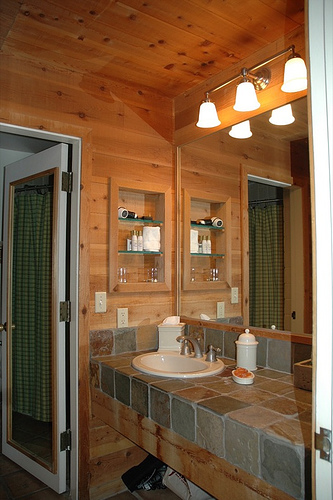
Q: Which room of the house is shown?
A: It is a bathroom.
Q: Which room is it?
A: It is a bathroom.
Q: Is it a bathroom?
A: Yes, it is a bathroom.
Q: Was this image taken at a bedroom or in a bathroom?
A: It was taken at a bathroom.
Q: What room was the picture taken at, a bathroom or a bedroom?
A: It was taken at a bathroom.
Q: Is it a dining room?
A: No, it is a bathroom.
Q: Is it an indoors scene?
A: Yes, it is indoors.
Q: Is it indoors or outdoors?
A: It is indoors.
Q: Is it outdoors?
A: No, it is indoors.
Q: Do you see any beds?
A: No, there are no beds.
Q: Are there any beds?
A: No, there are no beds.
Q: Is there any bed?
A: No, there are no beds.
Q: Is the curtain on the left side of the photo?
A: Yes, the curtain is on the left of the image.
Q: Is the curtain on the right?
A: No, the curtain is on the left of the image.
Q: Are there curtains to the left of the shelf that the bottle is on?
A: Yes, there is a curtain to the left of the shelf.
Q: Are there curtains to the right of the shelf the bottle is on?
A: No, the curtain is to the left of the shelf.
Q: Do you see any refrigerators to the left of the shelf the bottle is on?
A: No, there is a curtain to the left of the shelf.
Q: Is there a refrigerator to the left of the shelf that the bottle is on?
A: No, there is a curtain to the left of the shelf.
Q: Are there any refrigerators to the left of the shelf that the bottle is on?
A: No, there is a curtain to the left of the shelf.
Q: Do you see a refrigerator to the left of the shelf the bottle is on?
A: No, there is a curtain to the left of the shelf.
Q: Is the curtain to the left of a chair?
A: No, the curtain is to the left of the shelf.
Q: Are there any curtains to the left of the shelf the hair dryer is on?
A: Yes, there is a curtain to the left of the shelf.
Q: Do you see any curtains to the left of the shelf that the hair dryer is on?
A: Yes, there is a curtain to the left of the shelf.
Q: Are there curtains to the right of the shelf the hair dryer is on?
A: No, the curtain is to the left of the shelf.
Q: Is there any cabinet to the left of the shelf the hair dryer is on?
A: No, there is a curtain to the left of the shelf.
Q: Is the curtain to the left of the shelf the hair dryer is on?
A: Yes, the curtain is to the left of the shelf.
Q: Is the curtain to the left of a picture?
A: No, the curtain is to the left of the shelf.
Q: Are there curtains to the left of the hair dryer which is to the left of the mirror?
A: Yes, there is a curtain to the left of the hair dryer.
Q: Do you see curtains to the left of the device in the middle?
A: Yes, there is a curtain to the left of the hair dryer.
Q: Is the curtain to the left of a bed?
A: No, the curtain is to the left of a hair dryer.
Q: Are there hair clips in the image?
A: No, there are no hair clips.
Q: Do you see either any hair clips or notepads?
A: No, there are no hair clips or notepads.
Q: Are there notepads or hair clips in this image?
A: No, there are no hair clips or notepads.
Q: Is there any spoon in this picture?
A: No, there are no spoons.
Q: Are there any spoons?
A: No, there are no spoons.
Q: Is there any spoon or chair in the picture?
A: No, there are no spoons or chairs.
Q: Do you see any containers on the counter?
A: Yes, there is a container on the counter.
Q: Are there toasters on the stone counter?
A: No, there is a container on the counter.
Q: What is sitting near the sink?
A: The container is sitting near the sink.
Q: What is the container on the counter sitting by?
A: The container is sitting by the sink.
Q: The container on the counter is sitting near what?
A: The container is sitting by the sink.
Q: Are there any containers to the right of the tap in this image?
A: Yes, there is a container to the right of the tap.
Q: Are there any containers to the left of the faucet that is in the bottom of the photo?
A: No, the container is to the right of the faucet.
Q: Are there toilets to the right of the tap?
A: No, there is a container to the right of the tap.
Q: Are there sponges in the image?
A: No, there are no sponges.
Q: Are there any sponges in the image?
A: No, there are no sponges.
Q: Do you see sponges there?
A: No, there are no sponges.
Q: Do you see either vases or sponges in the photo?
A: No, there are no sponges or vases.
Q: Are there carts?
A: No, there are no carts.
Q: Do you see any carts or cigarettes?
A: No, there are no carts or cigarettes.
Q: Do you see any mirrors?
A: Yes, there is a mirror.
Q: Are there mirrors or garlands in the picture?
A: Yes, there is a mirror.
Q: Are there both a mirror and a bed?
A: No, there is a mirror but no beds.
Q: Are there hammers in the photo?
A: No, there are no hammers.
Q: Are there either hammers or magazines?
A: No, there are no hammers or magazines.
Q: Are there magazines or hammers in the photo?
A: No, there are no hammers or magazines.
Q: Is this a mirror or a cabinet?
A: This is a mirror.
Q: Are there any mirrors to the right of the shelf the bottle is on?
A: Yes, there is a mirror to the right of the shelf.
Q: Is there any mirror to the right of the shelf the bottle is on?
A: Yes, there is a mirror to the right of the shelf.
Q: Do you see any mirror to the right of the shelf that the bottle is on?
A: Yes, there is a mirror to the right of the shelf.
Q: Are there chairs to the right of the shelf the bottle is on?
A: No, there is a mirror to the right of the shelf.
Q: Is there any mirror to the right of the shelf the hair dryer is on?
A: Yes, there is a mirror to the right of the shelf.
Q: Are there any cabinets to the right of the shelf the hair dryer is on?
A: No, there is a mirror to the right of the shelf.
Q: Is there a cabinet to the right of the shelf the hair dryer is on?
A: No, there is a mirror to the right of the shelf.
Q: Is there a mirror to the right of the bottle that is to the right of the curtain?
A: Yes, there is a mirror to the right of the bottle.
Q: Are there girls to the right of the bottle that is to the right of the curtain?
A: No, there is a mirror to the right of the bottle.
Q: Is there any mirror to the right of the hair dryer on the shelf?
A: Yes, there is a mirror to the right of the hair dryer.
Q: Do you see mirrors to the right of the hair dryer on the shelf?
A: Yes, there is a mirror to the right of the hair dryer.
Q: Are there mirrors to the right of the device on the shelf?
A: Yes, there is a mirror to the right of the hair dryer.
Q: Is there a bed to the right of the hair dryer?
A: No, there is a mirror to the right of the hair dryer.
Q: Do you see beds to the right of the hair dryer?
A: No, there is a mirror to the right of the hair dryer.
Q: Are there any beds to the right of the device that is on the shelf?
A: No, there is a mirror to the right of the hair dryer.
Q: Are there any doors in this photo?
A: Yes, there is a door.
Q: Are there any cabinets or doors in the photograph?
A: Yes, there is a door.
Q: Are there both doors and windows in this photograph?
A: No, there is a door but no windows.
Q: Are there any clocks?
A: No, there are no clocks.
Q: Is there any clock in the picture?
A: No, there are no clocks.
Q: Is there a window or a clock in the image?
A: No, there are no clocks or windows.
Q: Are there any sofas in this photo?
A: No, there are no sofas.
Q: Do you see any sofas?
A: No, there are no sofas.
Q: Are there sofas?
A: No, there are no sofas.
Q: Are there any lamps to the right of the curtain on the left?
A: No, there is a shelf to the right of the curtain.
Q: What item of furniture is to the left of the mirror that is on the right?
A: The piece of furniture is a shelf.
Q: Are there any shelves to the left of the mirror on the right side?
A: Yes, there is a shelf to the left of the mirror.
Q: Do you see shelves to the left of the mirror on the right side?
A: Yes, there is a shelf to the left of the mirror.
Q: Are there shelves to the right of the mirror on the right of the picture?
A: No, the shelf is to the left of the mirror.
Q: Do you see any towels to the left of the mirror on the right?
A: No, there is a shelf to the left of the mirror.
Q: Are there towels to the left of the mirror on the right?
A: No, there is a shelf to the left of the mirror.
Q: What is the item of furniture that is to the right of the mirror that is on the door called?
A: The piece of furniture is a shelf.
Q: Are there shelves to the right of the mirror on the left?
A: Yes, there is a shelf to the right of the mirror.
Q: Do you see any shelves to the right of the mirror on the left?
A: Yes, there is a shelf to the right of the mirror.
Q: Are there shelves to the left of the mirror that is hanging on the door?
A: No, the shelf is to the right of the mirror.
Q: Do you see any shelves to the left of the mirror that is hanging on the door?
A: No, the shelf is to the right of the mirror.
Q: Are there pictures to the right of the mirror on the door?
A: No, there is a shelf to the right of the mirror.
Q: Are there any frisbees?
A: No, there are no frisbees.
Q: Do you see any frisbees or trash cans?
A: No, there are no frisbees or trash cans.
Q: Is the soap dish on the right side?
A: Yes, the soap dish is on the right of the image.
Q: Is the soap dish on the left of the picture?
A: No, the soap dish is on the right of the image.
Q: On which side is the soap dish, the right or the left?
A: The soap dish is on the right of the image.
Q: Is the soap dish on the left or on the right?
A: The soap dish is on the right of the image.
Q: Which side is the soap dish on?
A: The soap dish is on the right of the image.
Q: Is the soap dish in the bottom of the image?
A: Yes, the soap dish is in the bottom of the image.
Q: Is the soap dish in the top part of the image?
A: No, the soap dish is in the bottom of the image.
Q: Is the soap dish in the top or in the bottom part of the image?
A: The soap dish is in the bottom of the image.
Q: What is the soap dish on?
A: The soap dish is on the counter.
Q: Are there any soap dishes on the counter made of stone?
A: Yes, there is a soap dish on the counter.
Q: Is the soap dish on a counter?
A: Yes, the soap dish is on a counter.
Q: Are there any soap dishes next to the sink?
A: Yes, there is a soap dish next to the sink.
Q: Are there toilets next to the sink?
A: No, there is a soap dish next to the sink.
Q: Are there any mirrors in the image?
A: Yes, there is a mirror.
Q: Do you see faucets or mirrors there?
A: Yes, there is a mirror.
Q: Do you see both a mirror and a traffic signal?
A: No, there is a mirror but no traffic lights.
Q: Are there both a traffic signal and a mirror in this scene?
A: No, there is a mirror but no traffic lights.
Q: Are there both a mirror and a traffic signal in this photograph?
A: No, there is a mirror but no traffic lights.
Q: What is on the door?
A: The mirror is on the door.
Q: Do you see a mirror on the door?
A: Yes, there is a mirror on the door.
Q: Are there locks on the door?
A: No, there is a mirror on the door.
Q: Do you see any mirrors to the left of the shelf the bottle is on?
A: Yes, there is a mirror to the left of the shelf.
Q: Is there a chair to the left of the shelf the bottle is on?
A: No, there is a mirror to the left of the shelf.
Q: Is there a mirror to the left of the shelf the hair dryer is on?
A: Yes, there is a mirror to the left of the shelf.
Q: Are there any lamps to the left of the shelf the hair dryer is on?
A: No, there is a mirror to the left of the shelf.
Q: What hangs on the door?
A: The mirror hangs on the door.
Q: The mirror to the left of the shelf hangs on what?
A: The mirror hangs on the door.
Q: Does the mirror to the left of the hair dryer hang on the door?
A: Yes, the mirror hangs on the door.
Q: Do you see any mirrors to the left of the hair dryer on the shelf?
A: Yes, there is a mirror to the left of the hair dryer.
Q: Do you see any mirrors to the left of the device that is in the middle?
A: Yes, there is a mirror to the left of the hair dryer.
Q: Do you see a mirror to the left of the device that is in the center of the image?
A: Yes, there is a mirror to the left of the hair dryer.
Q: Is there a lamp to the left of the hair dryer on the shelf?
A: No, there is a mirror to the left of the hair dryer.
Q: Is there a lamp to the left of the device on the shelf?
A: No, there is a mirror to the left of the hair dryer.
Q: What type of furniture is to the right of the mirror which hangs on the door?
A: The piece of furniture is a shelf.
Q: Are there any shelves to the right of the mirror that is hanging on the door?
A: Yes, there is a shelf to the right of the mirror.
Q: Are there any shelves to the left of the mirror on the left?
A: No, the shelf is to the right of the mirror.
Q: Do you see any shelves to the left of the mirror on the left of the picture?
A: No, the shelf is to the right of the mirror.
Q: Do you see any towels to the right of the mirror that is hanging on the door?
A: No, there is a shelf to the right of the mirror.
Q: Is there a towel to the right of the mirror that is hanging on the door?
A: No, there is a shelf to the right of the mirror.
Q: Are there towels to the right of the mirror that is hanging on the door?
A: No, there is a shelf to the right of the mirror.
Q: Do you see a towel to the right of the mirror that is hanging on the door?
A: No, there is a shelf to the right of the mirror.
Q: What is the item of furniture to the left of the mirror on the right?
A: The piece of furniture is a shelf.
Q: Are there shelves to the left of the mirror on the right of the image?
A: Yes, there is a shelf to the left of the mirror.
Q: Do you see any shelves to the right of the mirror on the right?
A: No, the shelf is to the left of the mirror.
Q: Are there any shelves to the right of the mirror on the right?
A: No, the shelf is to the left of the mirror.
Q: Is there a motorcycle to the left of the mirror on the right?
A: No, there is a shelf to the left of the mirror.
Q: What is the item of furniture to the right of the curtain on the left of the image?
A: The piece of furniture is a shelf.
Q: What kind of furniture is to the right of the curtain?
A: The piece of furniture is a shelf.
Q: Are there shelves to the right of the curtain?
A: Yes, there is a shelf to the right of the curtain.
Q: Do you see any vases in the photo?
A: No, there are no vases.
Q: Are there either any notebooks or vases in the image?
A: No, there are no vases or notebooks.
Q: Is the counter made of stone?
A: Yes, the counter is made of stone.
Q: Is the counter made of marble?
A: No, the counter is made of stone.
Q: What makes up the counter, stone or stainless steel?
A: The counter is made of stone.